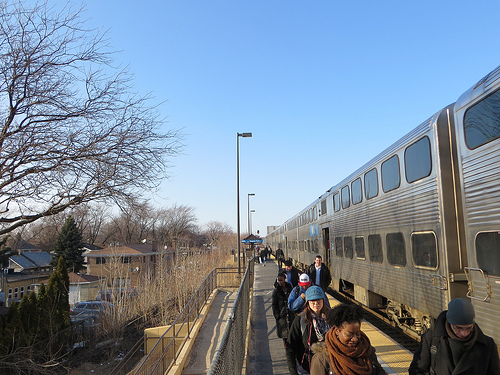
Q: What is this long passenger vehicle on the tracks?
A: Train.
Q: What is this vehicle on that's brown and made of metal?
A: Tracks.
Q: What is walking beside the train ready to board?
A: The people.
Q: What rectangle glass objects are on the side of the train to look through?
A: Windows.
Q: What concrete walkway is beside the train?
A: Sidewalk.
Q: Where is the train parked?
A: Tracks.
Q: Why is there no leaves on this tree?
A: They're dead.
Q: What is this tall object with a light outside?
A: Light pole.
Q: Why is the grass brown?
A: Dead.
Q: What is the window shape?
A: Square.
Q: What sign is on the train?
A: Blue.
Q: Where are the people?
A: Near train.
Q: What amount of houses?
A: Two.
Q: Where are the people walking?
A: Sidewalk.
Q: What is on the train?
A: Windows.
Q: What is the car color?
A: Silver.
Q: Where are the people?
A: Foreground.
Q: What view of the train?
A: Side.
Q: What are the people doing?
A: Walking.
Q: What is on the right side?
A: A train.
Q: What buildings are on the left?
A: Houses.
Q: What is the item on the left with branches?
A: A tree.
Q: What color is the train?
A: Silver.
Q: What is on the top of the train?
A: Windows.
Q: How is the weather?
A: Sunny and bright.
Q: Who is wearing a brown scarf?
A: The black lady.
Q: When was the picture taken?
A: During the day.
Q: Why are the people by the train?
A: They are boarding it.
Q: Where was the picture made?
A: At the train stop.